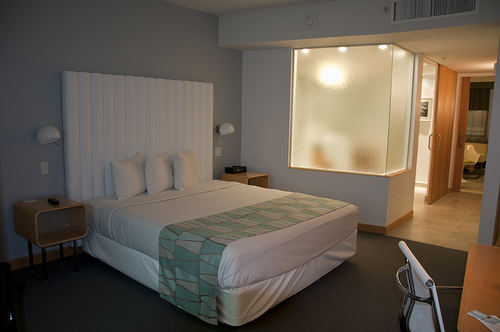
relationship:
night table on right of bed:
[9, 194, 91, 274] [69, 168, 365, 327]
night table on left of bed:
[9, 192, 89, 267] [75, 151, 360, 318]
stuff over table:
[223, 160, 250, 177] [227, 167, 279, 198]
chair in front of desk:
[374, 232, 455, 329] [455, 235, 500, 331]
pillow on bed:
[169, 145, 204, 195] [59, 74, 360, 330]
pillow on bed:
[143, 145, 173, 197] [59, 74, 360, 330]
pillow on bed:
[107, 146, 144, 203] [59, 74, 360, 330]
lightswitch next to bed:
[35, 157, 54, 177] [59, 74, 360, 330]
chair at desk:
[391, 239, 463, 331] [455, 235, 484, 313]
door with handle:
[425, 69, 459, 205] [435, 130, 440, 151]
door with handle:
[451, 83, 471, 193] [458, 134, 463, 147]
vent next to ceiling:
[390, 0, 495, 38] [173, 5, 387, 17]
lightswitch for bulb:
[38, 161, 50, 175] [35, 125, 62, 147]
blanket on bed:
[146, 196, 353, 269] [59, 74, 360, 330]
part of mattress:
[149, 209, 178, 229] [82, 177, 357, 276]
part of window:
[399, 105, 413, 131] [286, 43, 417, 178]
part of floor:
[430, 204, 468, 228] [382, 184, 480, 250]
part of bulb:
[44, 133, 61, 144] [32, 123, 66, 151]